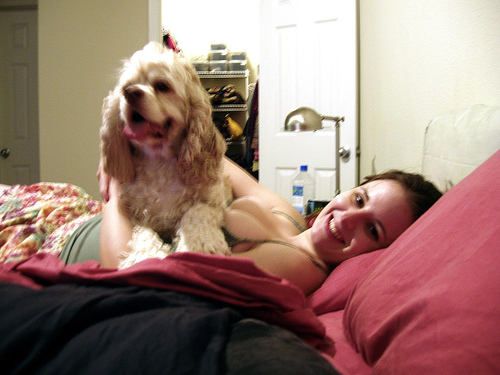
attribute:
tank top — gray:
[70, 207, 101, 258]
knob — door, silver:
[335, 142, 350, 166]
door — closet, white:
[267, 14, 368, 197]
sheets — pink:
[0, 249, 339, 354]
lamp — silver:
[278, 104, 343, 193]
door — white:
[243, 0, 362, 230]